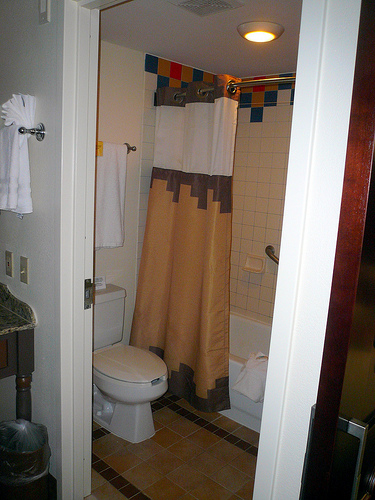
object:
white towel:
[0, 93, 36, 214]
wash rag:
[235, 349, 270, 404]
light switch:
[20, 255, 28, 284]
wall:
[0, 1, 65, 488]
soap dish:
[242, 252, 266, 275]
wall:
[229, 70, 295, 326]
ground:
[249, 100, 283, 151]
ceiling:
[102, 0, 304, 89]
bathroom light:
[235, 18, 285, 44]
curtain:
[122, 76, 246, 414]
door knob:
[338, 415, 373, 498]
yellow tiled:
[247, 150, 260, 168]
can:
[2, 413, 51, 484]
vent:
[172, 2, 241, 17]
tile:
[263, 91, 278, 107]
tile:
[250, 107, 264, 123]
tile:
[250, 91, 264, 108]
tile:
[239, 92, 252, 108]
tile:
[252, 76, 265, 92]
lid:
[87, 344, 170, 389]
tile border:
[143, 51, 219, 86]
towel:
[93, 142, 129, 250]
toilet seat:
[92, 342, 168, 388]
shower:
[158, 94, 277, 389]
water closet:
[88, 279, 126, 351]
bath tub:
[217, 299, 289, 417]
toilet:
[86, 277, 171, 444]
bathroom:
[14, 0, 309, 493]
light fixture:
[236, 19, 285, 43]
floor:
[91, 384, 258, 499]